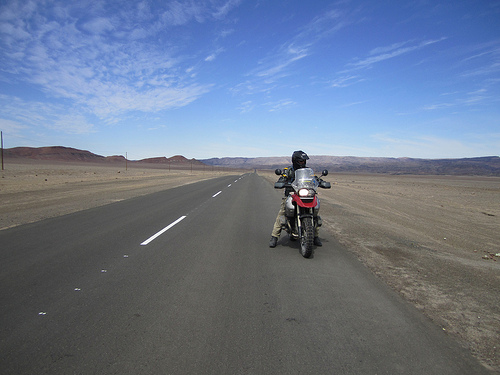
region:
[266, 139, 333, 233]
young man riding red colored motorcycle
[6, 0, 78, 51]
white clouds in blue sky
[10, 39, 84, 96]
white clouds in blue sky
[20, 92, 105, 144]
white clouds in blue sky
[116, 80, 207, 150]
white clouds in blue sky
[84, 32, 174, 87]
white clouds in blue sky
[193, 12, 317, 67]
white clouds in blue sky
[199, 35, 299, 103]
white clouds in blue sky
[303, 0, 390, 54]
white clouds in blue sky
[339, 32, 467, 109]
white clouds in blue sky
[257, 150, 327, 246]
red bike worn by person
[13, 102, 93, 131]
white clouds in blue sky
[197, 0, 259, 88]
white clouds in blue sky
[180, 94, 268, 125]
white clouds in blue sky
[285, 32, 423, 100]
white clouds in blue sky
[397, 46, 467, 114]
white clouds in blue sky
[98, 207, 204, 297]
road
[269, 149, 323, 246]
man sitting on a motorcycle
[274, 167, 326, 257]
a small motorcycle stopped along the road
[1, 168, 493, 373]
an empty, paved road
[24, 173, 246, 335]
white lines in the road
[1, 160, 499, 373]
a quiet desert scene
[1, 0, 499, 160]
a blue sky above the desert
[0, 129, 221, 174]
telephone poles in the desert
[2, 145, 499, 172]
hills behind the man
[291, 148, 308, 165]
black helmet on the man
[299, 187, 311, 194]
headlight of motorcycle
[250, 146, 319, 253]
person riding motorcycle on road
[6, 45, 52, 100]
white clouds in blue sky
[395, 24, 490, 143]
white clouds in blue sky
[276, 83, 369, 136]
white clouds in blue sky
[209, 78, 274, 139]
white clouds in blue sky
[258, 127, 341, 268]
person riding red motorcycle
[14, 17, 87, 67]
white clouds in blue sky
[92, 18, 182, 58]
white clouds in blue sky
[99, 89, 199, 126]
white clouds in blue sky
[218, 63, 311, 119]
white clouds in blue sky